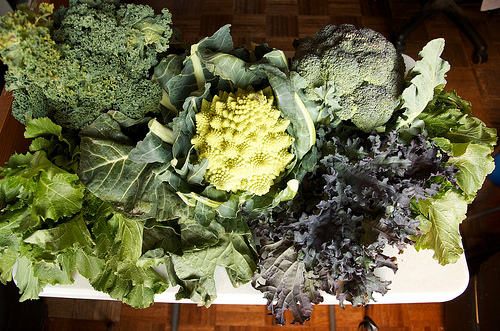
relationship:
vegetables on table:
[2, 10, 497, 318] [2, 15, 489, 300]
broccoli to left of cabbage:
[27, 8, 184, 123] [132, 26, 315, 219]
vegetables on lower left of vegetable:
[0, 115, 173, 311] [164, 72, 299, 202]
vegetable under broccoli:
[255, 135, 472, 302] [292, 19, 406, 136]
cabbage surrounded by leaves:
[189, 78, 315, 219] [134, 25, 328, 259]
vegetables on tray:
[2, 10, 497, 318] [18, 181, 479, 319]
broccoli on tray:
[126, 2, 347, 322] [23, 195, 473, 312]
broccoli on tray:
[292, 10, 412, 140] [18, 181, 479, 319]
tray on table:
[7, 192, 467, 305] [2, 0, 497, 330]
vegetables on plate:
[2, 10, 497, 318] [10, 213, 475, 306]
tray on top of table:
[12, 192, 468, 305] [2, 0, 497, 330]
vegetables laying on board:
[2, 10, 497, 318] [25, 183, 485, 317]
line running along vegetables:
[35, 171, 75, 211] [0, 115, 173, 311]